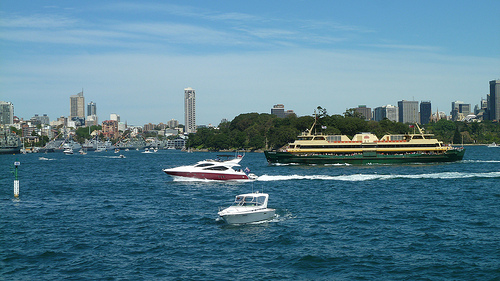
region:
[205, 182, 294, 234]
small white boat on the water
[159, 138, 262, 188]
red and white boat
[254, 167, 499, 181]
wake from the boat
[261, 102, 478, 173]
large boat on the water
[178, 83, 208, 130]
tall buiding in the distance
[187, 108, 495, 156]
thick green trees along the shore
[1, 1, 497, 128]
thin white clouds in the sky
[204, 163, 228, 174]
window on the side of the boat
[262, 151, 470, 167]
bottom of the boat is green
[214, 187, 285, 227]
gray and white boat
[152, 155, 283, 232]
boats in the water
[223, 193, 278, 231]
a white boat in the water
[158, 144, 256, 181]
a white and red boat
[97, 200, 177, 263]
choppiness on the surface of the water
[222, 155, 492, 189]
the wake in the water from a boat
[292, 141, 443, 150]
side windows on a boat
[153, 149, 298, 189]
a boat driving through the water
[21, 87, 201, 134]
the buildings of a city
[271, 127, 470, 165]
a green and tan boat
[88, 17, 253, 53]
clouds in the sky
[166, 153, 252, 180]
A red and white boat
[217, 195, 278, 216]
A white boat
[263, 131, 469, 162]
A red and green boat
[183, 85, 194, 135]
A skyscrapper in the city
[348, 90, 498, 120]
A city sky line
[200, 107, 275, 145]
Large green trees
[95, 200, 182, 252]
Blue ocean water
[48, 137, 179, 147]
Boats near the shore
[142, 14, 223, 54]
Thin clouds in the sky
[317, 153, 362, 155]
People on the large boat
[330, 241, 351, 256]
wave in the water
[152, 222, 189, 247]
wave in the water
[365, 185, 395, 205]
wave in the water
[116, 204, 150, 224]
wave in the water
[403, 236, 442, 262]
wave in the water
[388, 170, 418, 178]
wave in the water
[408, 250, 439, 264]
wave in the water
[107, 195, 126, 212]
wave in the water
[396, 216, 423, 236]
wave in the water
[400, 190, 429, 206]
wave in the water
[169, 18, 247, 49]
White wispy clouds in sky.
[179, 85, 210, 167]
Tall white building in distance.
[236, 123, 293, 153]
Many green trees in distance.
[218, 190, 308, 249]
White boat driving in water.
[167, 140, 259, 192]
Red and white boat in water.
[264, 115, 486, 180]
Large ship in water.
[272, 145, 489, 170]
Bottom of ship is green.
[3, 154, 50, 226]
White object sticking out of water.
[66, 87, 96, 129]
Tall tan building in distance.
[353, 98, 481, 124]
Many buildings in distance.